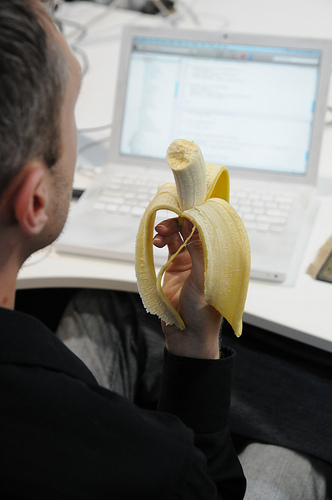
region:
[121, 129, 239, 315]
man holding a banana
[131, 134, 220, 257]
man holding a banana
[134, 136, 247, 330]
man holding a banana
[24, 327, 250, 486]
the suit is black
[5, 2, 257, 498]
a man eating a banana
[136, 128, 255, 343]
the banana is half-eaten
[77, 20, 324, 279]
a laptop on the desk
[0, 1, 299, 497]
a man looking at the computer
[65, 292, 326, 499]
the man is wearing jeans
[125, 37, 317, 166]
a window open on the laptop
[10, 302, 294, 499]
his jacket is dark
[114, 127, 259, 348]
the banana is yellow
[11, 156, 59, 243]
he has a right ear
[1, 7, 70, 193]
his hair is black and grey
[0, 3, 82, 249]
this is a man's head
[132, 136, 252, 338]
this is a peeled banana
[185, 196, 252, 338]
this is a banana peel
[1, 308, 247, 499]
he has on a black jacket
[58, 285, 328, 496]
he has on gray pants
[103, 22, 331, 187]
this is the computer screen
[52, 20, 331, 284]
this is a laptop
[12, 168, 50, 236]
this is his right ear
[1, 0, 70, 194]
this is his hair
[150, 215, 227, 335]
that's the man hand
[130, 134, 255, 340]
this banana looks pretty perfect in appearance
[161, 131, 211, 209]
the gentleman has eaten half the banana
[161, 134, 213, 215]
no bruises are visible on this banana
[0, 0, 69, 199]
the banana eater has salt and pepper hair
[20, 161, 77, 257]
the banana eater is showing some beard stubble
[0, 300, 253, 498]
the gentleman is wearing a black dress shirt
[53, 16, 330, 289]
the gentleman's computer is powered up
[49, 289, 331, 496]
the gentleman is wearing gray slacks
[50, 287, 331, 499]
the gentleman's legs are crossed under the table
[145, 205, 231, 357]
the gentleman is holding the banana in his right hand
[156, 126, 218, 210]
the fruit part of a banana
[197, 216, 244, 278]
the inside of a banana peel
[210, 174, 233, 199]
the outside of the banana peel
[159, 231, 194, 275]
a string coming off of a banana peel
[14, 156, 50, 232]
the ear of a grown man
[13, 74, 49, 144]
the hair of a grown man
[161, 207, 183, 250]
the finger of a grown man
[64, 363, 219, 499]
the shoulder of a grown man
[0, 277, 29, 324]
the neck of a grown man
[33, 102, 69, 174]
the sideburn of a grown man